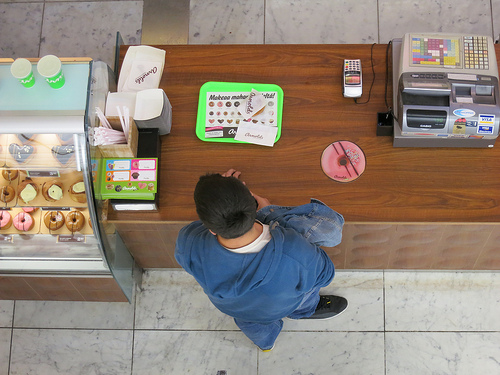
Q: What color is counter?
A: Brown.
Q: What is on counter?
A: Cash Register, Napkins, Straws.